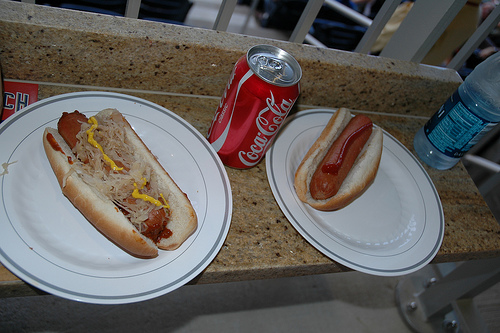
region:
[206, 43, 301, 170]
a can of Coca-Cola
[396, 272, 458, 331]
the round metal base of a table leg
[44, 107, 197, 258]
a hot dog with sauerkraut and mustard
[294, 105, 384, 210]
a hot dog with ketchup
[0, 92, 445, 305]
two plates with hot dogs on a counter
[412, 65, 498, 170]
a bottle of water on the counter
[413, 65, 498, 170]
a Dasani bottle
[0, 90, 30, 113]
the letters C and H in blue type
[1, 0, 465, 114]
the back ledge of a counter top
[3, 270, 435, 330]
the shadow of two plates on the floor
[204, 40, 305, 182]
a closed can of soda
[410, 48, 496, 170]
Dasani bottle of water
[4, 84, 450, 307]
two plates with hotdogs on them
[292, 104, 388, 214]
Hotdog on a bun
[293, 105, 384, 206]
hotdog with ketchup on it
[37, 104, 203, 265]
a hotdog with soukrout and mustard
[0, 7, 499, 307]
food and drink on a counter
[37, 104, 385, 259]
two hotdogs on a bun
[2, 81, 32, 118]
the letters CH in blue and white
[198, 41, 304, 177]
a can of coca cola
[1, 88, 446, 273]
white plates on the counter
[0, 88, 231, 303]
The white plate is plain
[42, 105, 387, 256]
hotdogs are on the plates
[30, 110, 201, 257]
sauerkraut and mustard are on the hotdog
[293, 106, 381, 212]
Hotdog only has ketchup on it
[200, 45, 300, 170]
can of soda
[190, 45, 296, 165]
the soda is coca cola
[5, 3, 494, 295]
The counter top is tan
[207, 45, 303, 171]
the soda can is red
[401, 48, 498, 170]
a water bottle on the counter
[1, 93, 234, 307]
Hot dog on a plate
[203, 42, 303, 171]
A Coca Cola soda can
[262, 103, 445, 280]
A plate is white and round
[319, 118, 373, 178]
Red ketchup on hot dog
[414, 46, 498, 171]
A bottle of water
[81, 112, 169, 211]
Yellow mustard on a hot dog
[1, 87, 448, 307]
Two plates on a countertop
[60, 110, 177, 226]
Sauer kraut on the hot dog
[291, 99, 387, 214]
Hot dog in a bun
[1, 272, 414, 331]
A shadow on the floor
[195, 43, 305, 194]
a drink can on a table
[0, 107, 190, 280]
a hot dog on a plate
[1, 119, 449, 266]
two hot dogs on plates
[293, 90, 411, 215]
a hot dog on a bun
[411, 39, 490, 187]
a clear water bottle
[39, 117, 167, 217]
a hot dog with mustard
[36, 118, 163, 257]
a hot dog with sour kraut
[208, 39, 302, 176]
a unopened drink can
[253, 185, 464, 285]
a white plate with grey trim